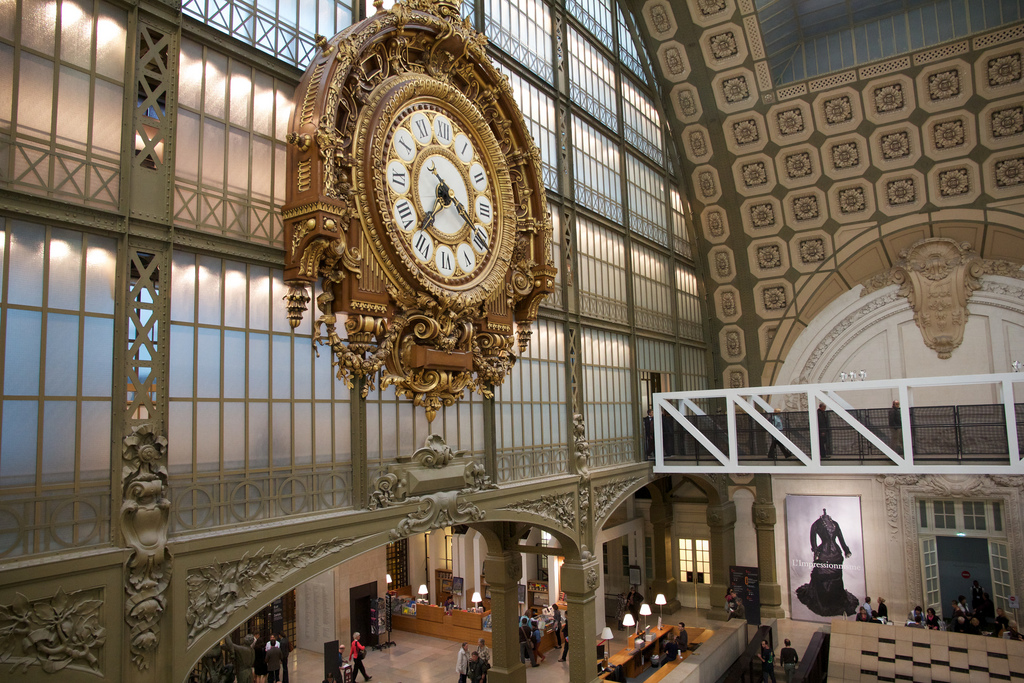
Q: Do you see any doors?
A: Yes, there is a door.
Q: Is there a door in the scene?
A: Yes, there is a door.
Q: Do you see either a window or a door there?
A: Yes, there is a door.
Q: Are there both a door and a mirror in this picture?
A: No, there is a door but no mirrors.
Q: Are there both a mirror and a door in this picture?
A: No, there is a door but no mirrors.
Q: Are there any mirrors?
A: No, there are no mirrors.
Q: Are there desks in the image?
A: Yes, there is a desk.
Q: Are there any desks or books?
A: Yes, there is a desk.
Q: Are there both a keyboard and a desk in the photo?
A: No, there is a desk but no keyboards.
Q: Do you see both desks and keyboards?
A: No, there is a desk but no keyboards.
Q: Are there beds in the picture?
A: No, there are no beds.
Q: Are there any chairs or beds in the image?
A: No, there are no beds or chairs.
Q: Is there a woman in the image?
A: Yes, there is a woman.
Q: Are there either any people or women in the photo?
A: Yes, there is a woman.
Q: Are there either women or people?
A: Yes, there is a woman.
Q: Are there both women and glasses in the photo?
A: No, there is a woman but no glasses.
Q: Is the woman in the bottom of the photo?
A: Yes, the woman is in the bottom of the image.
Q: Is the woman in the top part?
A: No, the woman is in the bottom of the image.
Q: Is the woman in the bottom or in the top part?
A: The woman is in the bottom of the image.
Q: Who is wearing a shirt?
A: The woman is wearing a shirt.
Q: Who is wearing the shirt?
A: The woman is wearing a shirt.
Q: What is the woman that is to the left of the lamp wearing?
A: The woman is wearing a shirt.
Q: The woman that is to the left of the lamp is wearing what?
A: The woman is wearing a shirt.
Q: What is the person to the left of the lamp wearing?
A: The woman is wearing a shirt.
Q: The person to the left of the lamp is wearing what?
A: The woman is wearing a shirt.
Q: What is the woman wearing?
A: The woman is wearing a shirt.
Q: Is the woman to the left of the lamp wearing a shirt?
A: Yes, the woman is wearing a shirt.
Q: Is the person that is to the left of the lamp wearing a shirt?
A: Yes, the woman is wearing a shirt.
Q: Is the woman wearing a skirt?
A: No, the woman is wearing a shirt.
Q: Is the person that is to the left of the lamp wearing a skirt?
A: No, the woman is wearing a shirt.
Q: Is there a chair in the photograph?
A: No, there are no chairs.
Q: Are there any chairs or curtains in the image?
A: No, there are no chairs or curtains.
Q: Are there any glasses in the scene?
A: No, there are no glasses.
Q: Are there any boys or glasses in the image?
A: No, there are no glasses or boys.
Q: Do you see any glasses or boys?
A: No, there are no glasses or boys.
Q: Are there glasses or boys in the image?
A: No, there are no glasses or boys.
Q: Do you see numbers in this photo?
A: Yes, there are numbers.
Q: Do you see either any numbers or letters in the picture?
A: Yes, there are numbers.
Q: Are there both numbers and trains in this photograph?
A: No, there are numbers but no trains.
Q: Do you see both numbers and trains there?
A: No, there are numbers but no trains.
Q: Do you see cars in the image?
A: No, there are no cars.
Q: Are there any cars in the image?
A: No, there are no cars.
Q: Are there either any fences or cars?
A: No, there are no cars or fences.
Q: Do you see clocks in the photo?
A: Yes, there is a clock.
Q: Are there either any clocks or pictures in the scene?
A: Yes, there is a clock.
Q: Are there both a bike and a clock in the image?
A: No, there is a clock but no bikes.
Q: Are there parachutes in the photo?
A: No, there are no parachutes.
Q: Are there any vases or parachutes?
A: No, there are no parachutes or vases.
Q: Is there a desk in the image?
A: Yes, there is a desk.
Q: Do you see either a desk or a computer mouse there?
A: Yes, there is a desk.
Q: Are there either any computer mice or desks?
A: Yes, there is a desk.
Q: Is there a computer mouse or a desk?
A: Yes, there is a desk.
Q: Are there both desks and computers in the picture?
A: No, there is a desk but no computers.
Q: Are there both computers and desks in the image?
A: No, there is a desk but no computers.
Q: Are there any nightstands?
A: No, there are no nightstands.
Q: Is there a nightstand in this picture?
A: No, there are no nightstands.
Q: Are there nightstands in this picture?
A: No, there are no nightstands.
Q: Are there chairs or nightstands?
A: No, there are no nightstands or chairs.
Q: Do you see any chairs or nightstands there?
A: No, there are no nightstands or chairs.